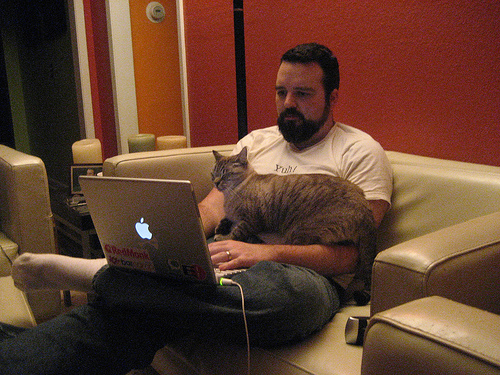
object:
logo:
[134, 217, 152, 240]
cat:
[208, 146, 379, 304]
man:
[9, 41, 394, 375]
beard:
[276, 96, 330, 143]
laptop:
[78, 174, 252, 285]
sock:
[12, 252, 108, 293]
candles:
[70, 134, 189, 165]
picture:
[70, 163, 103, 193]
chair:
[96, 142, 500, 375]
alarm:
[149, 2, 164, 22]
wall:
[73, 2, 499, 167]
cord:
[218, 277, 252, 375]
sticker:
[104, 243, 157, 274]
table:
[50, 196, 104, 264]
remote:
[344, 316, 370, 346]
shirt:
[229, 120, 396, 290]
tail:
[353, 212, 376, 306]